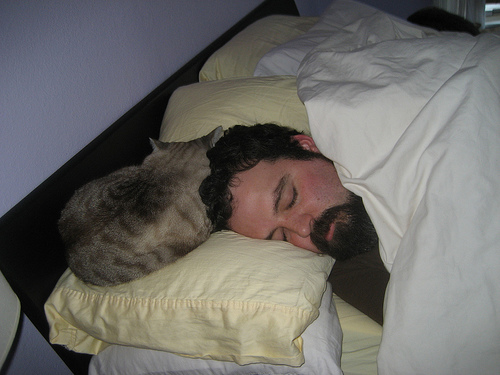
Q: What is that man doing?
A: Sleeping.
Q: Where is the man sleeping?
A: In a bed.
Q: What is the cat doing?
A: Sleeping.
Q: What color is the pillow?
A: Yellow.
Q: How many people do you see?
A: One.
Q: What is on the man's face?
A: Beard and mustache.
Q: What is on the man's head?
A: A cat.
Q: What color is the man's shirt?
A: Brown.